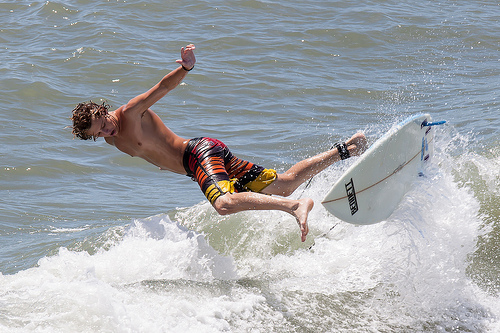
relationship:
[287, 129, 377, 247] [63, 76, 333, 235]
feet of person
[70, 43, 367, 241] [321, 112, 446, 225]
dude falling off surfboard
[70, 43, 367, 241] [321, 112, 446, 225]
dude from a surfboard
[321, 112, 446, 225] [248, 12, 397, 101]
surfboard into ocean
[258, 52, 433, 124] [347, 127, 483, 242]
water splashing surfboard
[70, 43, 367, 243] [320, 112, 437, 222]
dude on surfboard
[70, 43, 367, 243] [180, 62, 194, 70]
dude wears watch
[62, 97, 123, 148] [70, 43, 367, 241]
head of dude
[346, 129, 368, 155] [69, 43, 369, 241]
foot of person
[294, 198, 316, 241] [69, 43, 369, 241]
feet of person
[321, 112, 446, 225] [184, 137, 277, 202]
surfboard wearing multicolored trunks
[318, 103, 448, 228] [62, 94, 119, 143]
surfboard has hair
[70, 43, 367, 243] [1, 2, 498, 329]
dude into water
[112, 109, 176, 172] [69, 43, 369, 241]
chest of person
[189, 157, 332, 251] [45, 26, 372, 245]
leg of person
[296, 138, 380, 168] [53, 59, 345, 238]
leg of person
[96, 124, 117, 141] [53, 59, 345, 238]
nose of person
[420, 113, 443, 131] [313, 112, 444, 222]
fin on surfboard